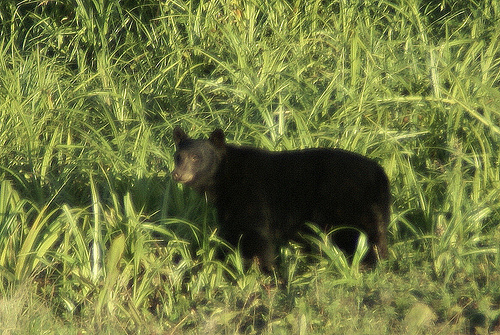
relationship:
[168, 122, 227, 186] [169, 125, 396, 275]
head of bear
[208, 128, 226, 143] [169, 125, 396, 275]
ear of bear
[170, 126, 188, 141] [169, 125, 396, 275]
ear of bear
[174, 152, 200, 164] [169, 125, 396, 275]
eyes of bear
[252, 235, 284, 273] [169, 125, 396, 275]
leg of bear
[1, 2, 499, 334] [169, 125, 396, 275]
grass with bear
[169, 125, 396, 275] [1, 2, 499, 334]
bear standing in grass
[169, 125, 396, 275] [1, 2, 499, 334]
bear on top of grass